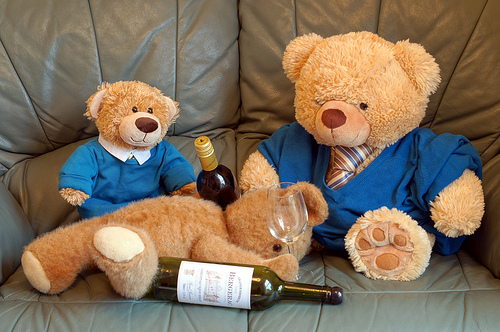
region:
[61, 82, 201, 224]
a small brown plush teddy bear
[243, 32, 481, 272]
a large brown plush teddy bear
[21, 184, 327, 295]
a brown plush teddy bear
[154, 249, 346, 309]
a green bottle of wine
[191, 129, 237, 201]
a green bottle of wine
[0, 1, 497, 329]
a grey leather couch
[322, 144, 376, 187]
a colorful tie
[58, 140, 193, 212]
a blue teddy tear shirt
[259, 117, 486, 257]
a blue teddy tear shirt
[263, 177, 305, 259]
a empty clear drinking glass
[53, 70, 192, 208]
SMALL BROWN TEDDY BEAR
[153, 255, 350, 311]
EMPTY WINE BOTTLE ON CUSHION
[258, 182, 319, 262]
EMPTY WINE GLASS IN TEDDY'S HAND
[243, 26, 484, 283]
LARGE BROWN TEDDY BEAR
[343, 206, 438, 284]
PAW OF LARGE BEAR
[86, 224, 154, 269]
PAW OF INTOXICATED BEAR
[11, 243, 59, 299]
PAW OF INTOXICATED BEAR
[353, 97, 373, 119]
EYE OF LARGE BEAR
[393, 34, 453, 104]
EAR OF LARGE BEAR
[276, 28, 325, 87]
EAR OF LARGE BEAR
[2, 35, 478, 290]
3 bears on couch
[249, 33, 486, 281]
big teddy bear on couch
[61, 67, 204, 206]
small brown bear on couch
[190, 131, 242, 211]
bottle of conac on couch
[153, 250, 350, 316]
green wine bottle on couch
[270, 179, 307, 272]
clear wine glass in hand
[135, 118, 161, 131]
brown nose on the bear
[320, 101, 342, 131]
brown nose on the big bear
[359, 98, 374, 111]
left eye on bear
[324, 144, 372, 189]
tie on the bigger bear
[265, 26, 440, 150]
brown head of teddy bear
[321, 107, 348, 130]
brown nose of teddy bear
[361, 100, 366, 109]
black eye of teddy bear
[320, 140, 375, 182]
tie on front of bear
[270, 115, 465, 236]
blue shirt on teddy bear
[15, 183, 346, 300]
teddy bear laying down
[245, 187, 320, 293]
hand holding glass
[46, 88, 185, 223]
teddy bear dressed up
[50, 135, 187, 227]
blue and white shirt on bear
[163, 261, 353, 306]
knocked over bottle of wine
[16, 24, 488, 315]
Teddy bears on the couch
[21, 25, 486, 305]
Teddy bears are on the couch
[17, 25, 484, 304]
Stuffed animals on the couch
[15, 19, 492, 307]
Stuffed animals are on the couch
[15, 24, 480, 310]
Stuffed bears on the couch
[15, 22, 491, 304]
Stuffed bears are on the couch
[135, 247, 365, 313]
Bottle on the couch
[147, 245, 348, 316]
Bottle is on the couch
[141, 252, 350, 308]
Wine bottle on the couch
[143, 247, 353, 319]
Wine bottle is on the couch